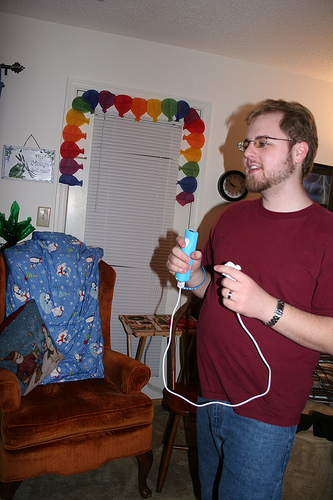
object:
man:
[166, 98, 332, 499]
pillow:
[2, 298, 64, 397]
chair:
[1, 258, 154, 500]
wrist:
[262, 294, 294, 334]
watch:
[264, 298, 285, 328]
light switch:
[36, 206, 52, 227]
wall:
[1, 13, 332, 388]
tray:
[118, 312, 198, 338]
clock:
[217, 169, 249, 203]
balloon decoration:
[60, 89, 206, 207]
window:
[78, 95, 202, 383]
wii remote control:
[161, 230, 272, 409]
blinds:
[83, 111, 183, 376]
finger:
[221, 287, 239, 302]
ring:
[227, 290, 233, 300]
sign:
[0, 144, 58, 185]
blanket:
[3, 229, 106, 384]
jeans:
[194, 395, 298, 499]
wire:
[161, 284, 271, 410]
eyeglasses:
[237, 134, 301, 152]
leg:
[135, 449, 156, 500]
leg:
[1, 480, 24, 500]